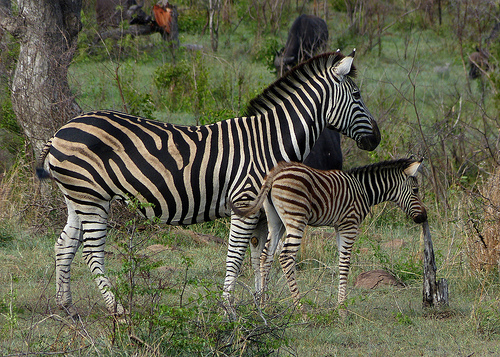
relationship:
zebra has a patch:
[35, 47, 381, 323] [249, 236, 261, 251]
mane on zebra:
[352, 157, 416, 175] [227, 154, 428, 324]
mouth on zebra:
[409, 207, 428, 224] [227, 154, 428, 324]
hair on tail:
[226, 196, 247, 220] [225, 162, 282, 222]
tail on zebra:
[225, 162, 282, 222] [227, 154, 428, 324]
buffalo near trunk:
[274, 15, 329, 78] [149, 2, 181, 53]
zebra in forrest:
[227, 154, 428, 324] [1, 0, 500, 356]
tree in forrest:
[1, 0, 159, 235] [1, 0, 500, 356]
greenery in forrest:
[1, 0, 500, 356] [1, 0, 500, 356]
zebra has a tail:
[227, 154, 428, 324] [225, 162, 282, 222]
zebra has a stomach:
[35, 47, 381, 323] [115, 195, 230, 225]